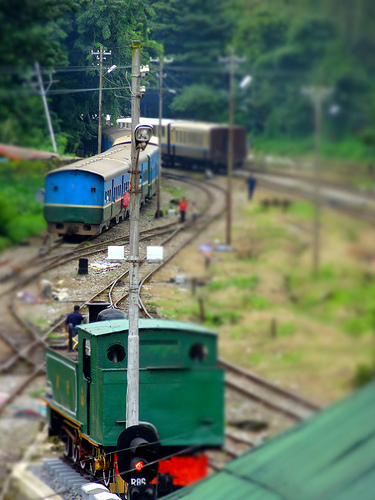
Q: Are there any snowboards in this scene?
A: No, there are no snowboards.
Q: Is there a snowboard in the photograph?
A: No, there are no snowboards.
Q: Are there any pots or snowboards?
A: No, there are no snowboards or pots.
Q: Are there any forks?
A: No, there are no forks.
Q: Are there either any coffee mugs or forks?
A: No, there are no forks or coffee mugs.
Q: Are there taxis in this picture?
A: Yes, there is a taxi.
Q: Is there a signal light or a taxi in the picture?
A: Yes, there is a taxi.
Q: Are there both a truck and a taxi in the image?
A: No, there is a taxi but no trucks.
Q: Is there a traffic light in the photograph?
A: No, there are no traffic lights.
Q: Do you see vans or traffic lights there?
A: No, there are no traffic lights or vans.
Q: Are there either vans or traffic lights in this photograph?
A: No, there are no traffic lights or vans.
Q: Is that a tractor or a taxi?
A: That is a taxi.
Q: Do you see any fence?
A: No, there are no fences.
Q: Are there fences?
A: No, there are no fences.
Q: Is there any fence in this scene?
A: No, there are no fences.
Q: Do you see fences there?
A: No, there are no fences.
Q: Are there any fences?
A: No, there are no fences.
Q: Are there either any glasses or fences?
A: No, there are no fences or glasses.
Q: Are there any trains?
A: Yes, there is a train.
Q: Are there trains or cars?
A: Yes, there is a train.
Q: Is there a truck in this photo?
A: No, there are no trucks.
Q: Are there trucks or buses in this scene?
A: No, there are no trucks or buses.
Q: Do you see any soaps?
A: No, there are no soaps.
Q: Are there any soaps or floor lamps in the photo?
A: No, there are no soaps or floor lamps.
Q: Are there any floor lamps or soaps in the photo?
A: No, there are no soaps or floor lamps.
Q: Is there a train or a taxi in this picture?
A: Yes, there is a train.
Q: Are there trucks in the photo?
A: No, there are no trucks.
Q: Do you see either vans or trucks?
A: No, there are no trucks or vans.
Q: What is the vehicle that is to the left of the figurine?
A: The vehicle is a train.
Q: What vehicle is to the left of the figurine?
A: The vehicle is a train.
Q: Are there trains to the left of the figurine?
A: Yes, there is a train to the left of the figurine.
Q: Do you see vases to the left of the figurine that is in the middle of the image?
A: No, there is a train to the left of the figurine.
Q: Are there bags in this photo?
A: No, there are no bags.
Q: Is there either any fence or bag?
A: No, there are no bags or fences.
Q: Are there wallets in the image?
A: No, there are no wallets.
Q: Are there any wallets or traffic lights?
A: No, there are no wallets or traffic lights.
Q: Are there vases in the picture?
A: No, there are no vases.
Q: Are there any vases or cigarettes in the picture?
A: No, there are no vases or cigarettes.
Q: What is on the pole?
A: The wires are on the pole.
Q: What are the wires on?
A: The wires are on the pole.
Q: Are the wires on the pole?
A: Yes, the wires are on the pole.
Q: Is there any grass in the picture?
A: Yes, there is grass.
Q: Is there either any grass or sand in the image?
A: Yes, there is grass.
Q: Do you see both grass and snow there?
A: No, there is grass but no snow.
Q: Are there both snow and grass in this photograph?
A: No, there is grass but no snow.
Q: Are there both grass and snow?
A: No, there is grass but no snow.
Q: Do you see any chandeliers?
A: No, there are no chandeliers.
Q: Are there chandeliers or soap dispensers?
A: No, there are no chandeliers or soap dispensers.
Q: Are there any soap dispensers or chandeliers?
A: No, there are no chandeliers or soap dispensers.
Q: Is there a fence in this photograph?
A: No, there are no fences.